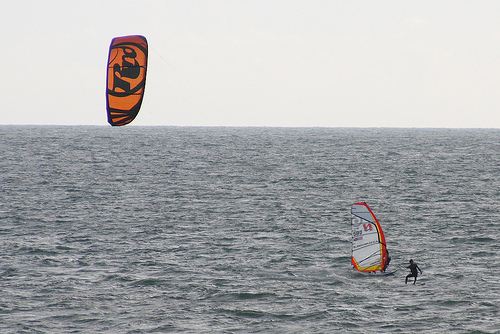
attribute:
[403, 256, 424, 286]
person — surfsailing, standing on somethin, standing, a person, a man, sea surfing, in motion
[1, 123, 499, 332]
water — dark, dark blue, grey, blue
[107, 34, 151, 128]
parasail — orange, big, white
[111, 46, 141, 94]
lettering — black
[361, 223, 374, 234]
numbers — orange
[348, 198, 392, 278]
parasail — orange, black, white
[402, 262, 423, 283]
wetsuit — black, dark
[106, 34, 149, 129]
trim — black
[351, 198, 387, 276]
trim — orange, red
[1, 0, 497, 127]
sky — light, overcast, full of clouds, white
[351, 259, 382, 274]
strip — yellow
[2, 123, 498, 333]
some ripples — small